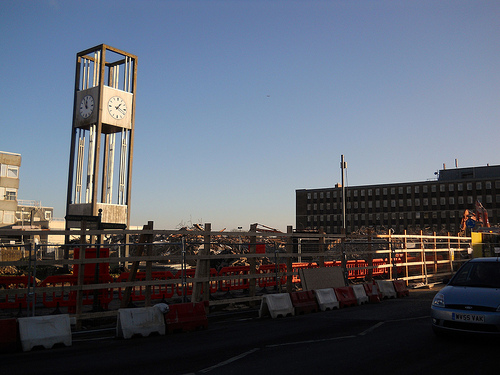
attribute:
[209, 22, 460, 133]
sky — blue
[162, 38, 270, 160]
sky — blue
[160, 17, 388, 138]
sky — blue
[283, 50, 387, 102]
sky — blue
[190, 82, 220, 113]
clouds — white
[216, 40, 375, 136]
sky — blue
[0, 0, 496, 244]
sky — blue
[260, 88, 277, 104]
cloud — white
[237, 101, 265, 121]
clouds — white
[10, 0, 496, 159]
sky — blue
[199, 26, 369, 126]
sky — blue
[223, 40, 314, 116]
sky — blue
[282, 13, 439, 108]
clouds — white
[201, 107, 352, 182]
clouds — white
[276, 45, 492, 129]
sky — blue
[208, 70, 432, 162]
clouds — white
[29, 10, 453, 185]
sky — blue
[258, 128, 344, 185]
clouds — white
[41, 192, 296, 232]
cloud — white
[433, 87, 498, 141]
clouds — white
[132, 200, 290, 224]
clouds — white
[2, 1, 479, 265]
sky — blue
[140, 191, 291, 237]
clouds — white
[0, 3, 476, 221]
sky — blue